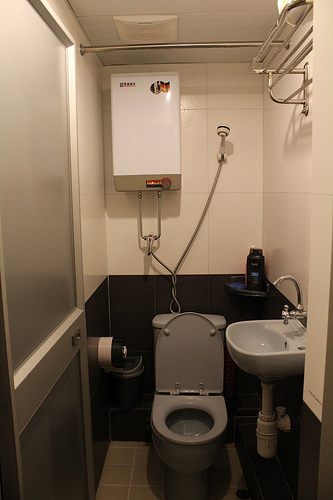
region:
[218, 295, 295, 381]
white ceramic hanging sink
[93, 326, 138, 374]
holder for paper towel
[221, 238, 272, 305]
black dove shampoo bottle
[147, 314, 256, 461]
gray colored toilet seat and cover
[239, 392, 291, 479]
pipes underneath sink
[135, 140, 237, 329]
shower head pull out cord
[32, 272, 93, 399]
white door with frosty glass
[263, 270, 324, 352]
silver rounded faucet head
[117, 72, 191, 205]
white box for water holding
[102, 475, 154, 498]
gray colored tile floor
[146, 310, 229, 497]
a grey porcelain toilet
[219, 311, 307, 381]
a white porcelain bathroom sink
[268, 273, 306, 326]
a chrome bathroom faucet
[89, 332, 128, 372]
a roll of toilet paper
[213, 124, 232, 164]
a wall mounted shower head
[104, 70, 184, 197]
a large white tank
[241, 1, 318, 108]
an overhead towel rack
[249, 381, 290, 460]
a white PVC pipe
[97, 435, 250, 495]
a brown tile floor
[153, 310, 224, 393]
an uplifted toilet seat lid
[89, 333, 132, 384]
toilet paper dispensor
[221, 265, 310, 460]
white porcelain sink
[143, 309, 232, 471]
a toilet with a U shaped seat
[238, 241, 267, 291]
black container of shampoo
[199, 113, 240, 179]
the shower head on the wall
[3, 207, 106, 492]
the bathroom door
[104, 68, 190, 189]
the water tank on the wall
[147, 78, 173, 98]
sticker with a German flag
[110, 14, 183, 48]
fan vent on the ceiling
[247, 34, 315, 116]
empty metal shelving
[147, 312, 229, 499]
The gray toilet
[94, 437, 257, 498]
The tiles on the ground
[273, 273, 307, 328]
The faucet over the sink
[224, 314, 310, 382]
The bowl of the sink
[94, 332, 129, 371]
The toilet paper holder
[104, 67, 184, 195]
The white box on the wall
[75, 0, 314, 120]
The silver rods on the walls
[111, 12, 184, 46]
The white vent on the ceiling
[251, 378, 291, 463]
The white pipe below the sink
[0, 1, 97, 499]
The gray door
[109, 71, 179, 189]
a white small water heater tank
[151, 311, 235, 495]
a gray toilet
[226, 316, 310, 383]
a white wall mounted sink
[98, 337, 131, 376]
a toilet paper holder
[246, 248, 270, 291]
a bottle of shower gel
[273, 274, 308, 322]
a silver faucet on a bathroom sink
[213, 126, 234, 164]
a white shower head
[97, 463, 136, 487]
a single beige tile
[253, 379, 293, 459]
drainage pipe on a sink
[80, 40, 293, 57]
a silver shower curtain rod